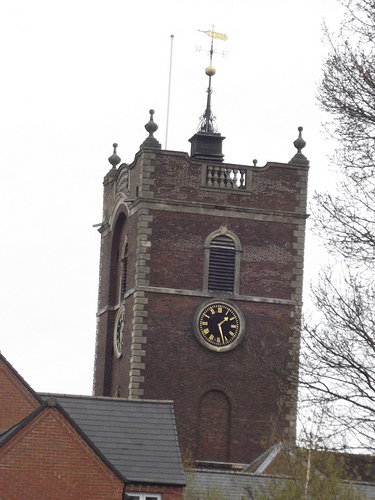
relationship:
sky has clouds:
[37, 192, 79, 264] [16, 177, 87, 294]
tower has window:
[90, 68, 309, 472] [200, 224, 243, 292]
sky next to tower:
[0, 0, 375, 292] [90, 68, 309, 472]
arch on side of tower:
[191, 384, 237, 467] [90, 68, 309, 472]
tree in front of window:
[297, 278, 374, 459] [199, 221, 245, 299]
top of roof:
[96, 145, 322, 213] [94, 103, 315, 226]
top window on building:
[124, 482, 177, 498] [1, 353, 192, 498]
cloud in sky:
[0, 0, 374, 452] [27, 27, 125, 119]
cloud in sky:
[0, 0, 374, 452] [0, 0, 375, 292]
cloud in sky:
[0, 0, 374, 452] [23, 58, 76, 107]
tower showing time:
[86, 68, 309, 471] [192, 297, 245, 351]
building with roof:
[1, 353, 192, 498] [26, 390, 189, 486]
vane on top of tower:
[193, 25, 243, 111] [86, 68, 309, 471]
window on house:
[121, 491, 163, 499] [1, 347, 186, 499]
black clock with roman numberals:
[195, 298, 247, 349] [200, 305, 239, 345]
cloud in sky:
[0, 0, 374, 452] [8, 14, 363, 365]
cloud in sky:
[5, 2, 374, 452] [36, 16, 359, 174]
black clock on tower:
[195, 298, 247, 349] [90, 68, 309, 472]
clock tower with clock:
[88, 42, 317, 359] [191, 296, 245, 351]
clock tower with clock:
[88, 42, 317, 359] [109, 302, 127, 358]